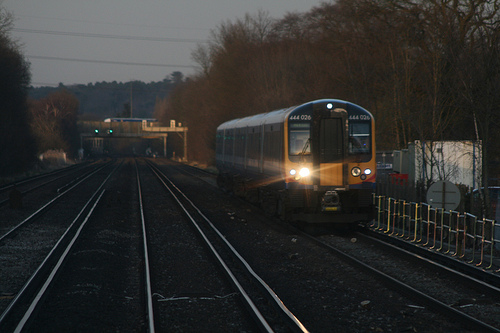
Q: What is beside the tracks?
A: Fence.